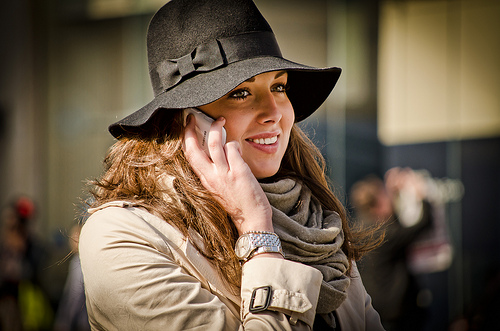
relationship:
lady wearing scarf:
[74, 0, 384, 331] [253, 175, 355, 322]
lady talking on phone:
[74, 0, 384, 331] [177, 104, 229, 163]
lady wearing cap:
[74, 0, 384, 331] [106, 0, 343, 142]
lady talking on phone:
[134, 0, 368, 327] [149, 75, 275, 192]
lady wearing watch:
[74, 0, 384, 331] [227, 230, 283, 258]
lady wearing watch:
[74, 0, 384, 331] [244, 244, 284, 257]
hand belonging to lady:
[181, 117, 276, 224] [74, 0, 384, 331]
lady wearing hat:
[74, 0, 384, 331] [131, 3, 369, 130]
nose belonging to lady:
[245, 79, 291, 138] [74, 0, 384, 331]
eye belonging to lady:
[227, 84, 253, 101] [74, 0, 384, 331]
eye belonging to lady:
[269, 81, 288, 91] [74, 0, 384, 331]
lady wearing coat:
[74, 0, 384, 331] [80, 202, 384, 324]